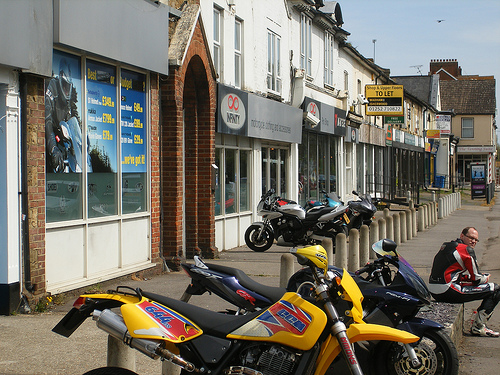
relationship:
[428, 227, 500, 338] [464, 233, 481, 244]
gear has glasses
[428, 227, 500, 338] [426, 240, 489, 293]
gear in jacket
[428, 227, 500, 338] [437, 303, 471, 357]
gear sitting on curb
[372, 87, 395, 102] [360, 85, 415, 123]
words written on sign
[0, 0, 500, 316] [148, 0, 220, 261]
building made of brick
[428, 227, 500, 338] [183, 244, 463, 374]
gear beside motorbike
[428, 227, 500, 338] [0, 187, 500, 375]
gear is on floor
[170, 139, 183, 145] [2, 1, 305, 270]
brick on building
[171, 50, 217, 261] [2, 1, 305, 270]
archway on building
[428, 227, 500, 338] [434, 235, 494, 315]
gear wearing gear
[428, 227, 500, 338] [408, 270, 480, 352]
gear sitting on curb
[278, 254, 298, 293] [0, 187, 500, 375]
barrier on floor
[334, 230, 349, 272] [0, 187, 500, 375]
barrier on floor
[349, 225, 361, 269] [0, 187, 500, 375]
barrier on floor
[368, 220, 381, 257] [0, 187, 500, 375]
barrier on floor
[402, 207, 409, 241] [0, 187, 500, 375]
barrier on floor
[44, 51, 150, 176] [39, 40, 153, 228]
poster on window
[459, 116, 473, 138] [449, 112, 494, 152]
window on wall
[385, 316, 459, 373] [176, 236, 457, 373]
tire on motorcycle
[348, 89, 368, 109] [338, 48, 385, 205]
camera on wall